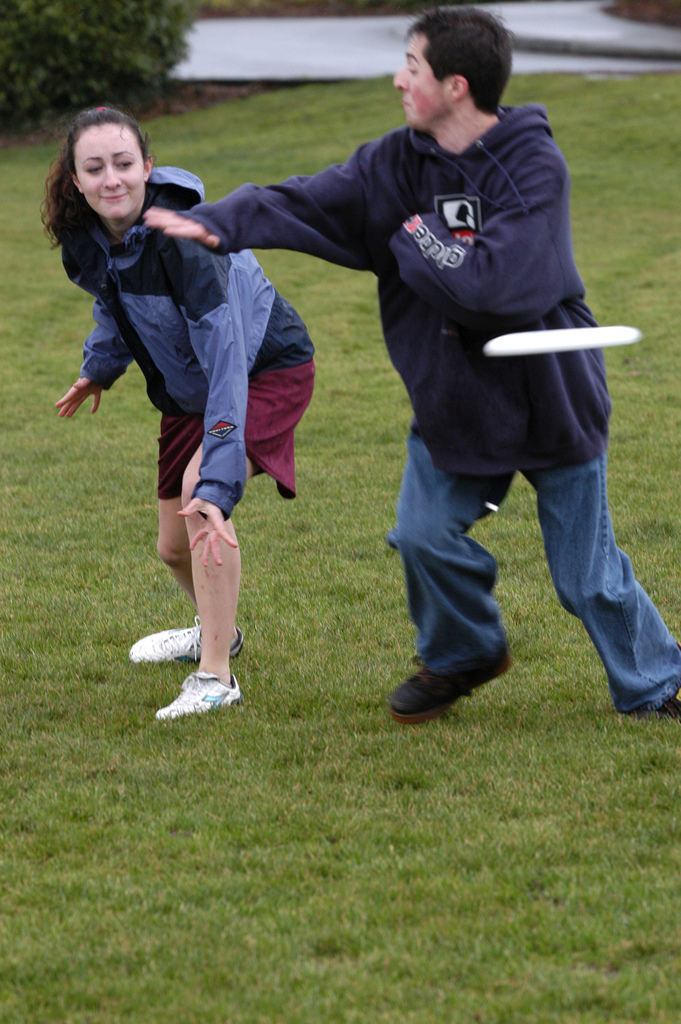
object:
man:
[142, 5, 680, 725]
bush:
[0, 0, 198, 132]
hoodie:
[172, 100, 613, 476]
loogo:
[434, 194, 483, 248]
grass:
[0, 72, 681, 1024]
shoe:
[389, 643, 513, 724]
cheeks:
[407, 65, 440, 120]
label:
[207, 420, 238, 440]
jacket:
[76, 165, 316, 522]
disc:
[483, 325, 643, 358]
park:
[3, 0, 681, 1024]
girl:
[39, 107, 315, 719]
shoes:
[129, 616, 244, 718]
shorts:
[157, 359, 316, 500]